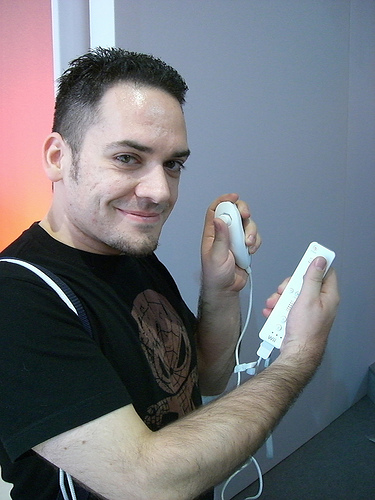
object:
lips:
[113, 207, 164, 226]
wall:
[178, 3, 366, 418]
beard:
[97, 231, 158, 254]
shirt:
[0, 218, 214, 500]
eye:
[111, 153, 144, 165]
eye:
[164, 161, 183, 176]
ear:
[41, 130, 65, 184]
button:
[217, 212, 232, 225]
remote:
[265, 234, 345, 370]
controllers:
[211, 199, 252, 271]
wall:
[3, 0, 52, 221]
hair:
[157, 431, 231, 445]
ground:
[220, 123, 241, 167]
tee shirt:
[90, 276, 167, 347]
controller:
[256, 237, 335, 360]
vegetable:
[249, 230, 345, 355]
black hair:
[50, 44, 190, 183]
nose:
[134, 166, 170, 205]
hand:
[200, 190, 261, 289]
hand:
[281, 256, 340, 364]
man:
[0, 42, 338, 500]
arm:
[164, 357, 318, 499]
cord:
[235, 267, 264, 371]